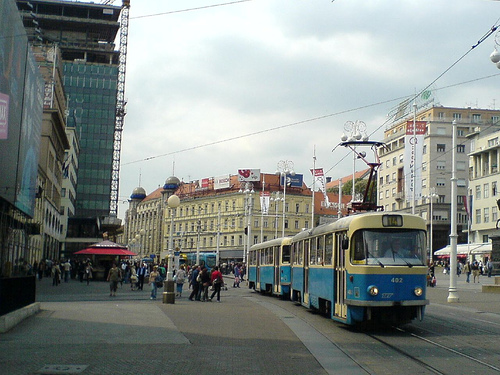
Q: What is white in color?
A: Clouds.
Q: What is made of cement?
A: The ground.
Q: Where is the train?
A: On the tracks.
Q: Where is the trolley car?
A: On the tracks.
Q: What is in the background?
A: Building.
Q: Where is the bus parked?
A: Near the sidewalk.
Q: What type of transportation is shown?
A: A trolley train.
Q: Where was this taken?
A: A city street.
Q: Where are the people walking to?
A: The trolley.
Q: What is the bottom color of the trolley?
A: Blue.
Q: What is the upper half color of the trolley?
A: Yellow.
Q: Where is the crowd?
A: On the sidewalk.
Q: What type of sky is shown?
A: Cloudy sky.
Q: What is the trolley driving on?
A: Tracks.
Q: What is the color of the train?
A: Blue.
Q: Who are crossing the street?
A: Crowd.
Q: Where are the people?
A: At the sidewalk.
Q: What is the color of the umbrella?
A: Red.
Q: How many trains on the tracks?
A: One.